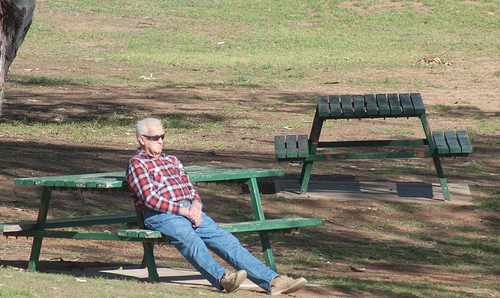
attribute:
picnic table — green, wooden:
[274, 89, 475, 200]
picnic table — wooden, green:
[2, 157, 336, 285]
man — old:
[117, 114, 315, 296]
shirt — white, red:
[142, 163, 240, 211]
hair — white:
[134, 115, 163, 138]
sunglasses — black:
[140, 135, 164, 142]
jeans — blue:
[136, 198, 278, 291]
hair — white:
[138, 111, 177, 169]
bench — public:
[1, 134, 333, 292]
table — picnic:
[267, 83, 456, 192]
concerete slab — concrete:
[272, 172, 477, 207]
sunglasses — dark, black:
[136, 130, 164, 142]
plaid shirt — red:
[124, 145, 204, 210]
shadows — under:
[321, 159, 425, 219]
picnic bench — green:
[268, 86, 479, 201]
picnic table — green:
[280, 104, 495, 179]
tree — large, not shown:
[0, 0, 37, 88]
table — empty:
[275, 91, 469, 195]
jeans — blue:
[139, 201, 292, 296]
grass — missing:
[413, 202, 482, 222]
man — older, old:
[127, 117, 309, 295]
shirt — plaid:
[127, 146, 200, 214]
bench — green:
[2, 165, 324, 279]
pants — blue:
[138, 200, 279, 291]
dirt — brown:
[359, 207, 430, 236]